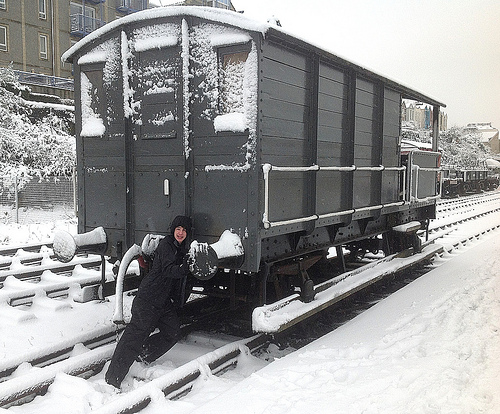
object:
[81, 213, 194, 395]
person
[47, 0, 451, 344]
train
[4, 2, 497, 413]
photo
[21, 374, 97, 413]
snow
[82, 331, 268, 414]
tracks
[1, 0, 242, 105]
building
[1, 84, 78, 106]
background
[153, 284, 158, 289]
black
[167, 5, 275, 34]
snow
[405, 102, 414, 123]
structures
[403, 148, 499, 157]
background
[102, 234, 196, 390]
snow suit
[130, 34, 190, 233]
door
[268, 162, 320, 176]
rails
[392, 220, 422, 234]
steps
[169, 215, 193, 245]
head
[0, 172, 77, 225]
fence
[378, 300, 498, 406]
footprints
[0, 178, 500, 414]
snow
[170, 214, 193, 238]
hood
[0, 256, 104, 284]
track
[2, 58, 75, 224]
tree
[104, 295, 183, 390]
pants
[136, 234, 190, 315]
coat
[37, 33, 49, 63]
windows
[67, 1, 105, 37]
balconies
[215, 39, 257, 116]
window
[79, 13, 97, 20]
snow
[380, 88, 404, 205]
deck